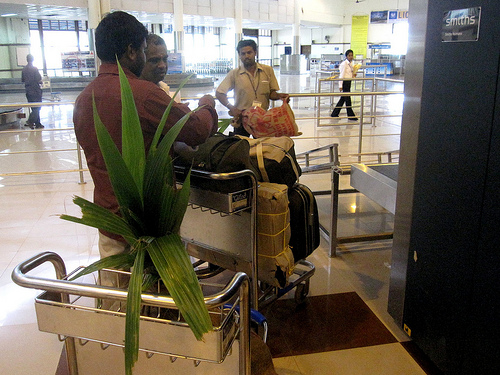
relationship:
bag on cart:
[193, 134, 262, 182] [171, 164, 317, 340]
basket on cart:
[94, 253, 171, 290] [6, 228, 260, 373]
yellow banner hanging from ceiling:
[350, 16, 370, 58] [116, 1, 407, 20]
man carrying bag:
[210, 33, 298, 137] [193, 134, 262, 182]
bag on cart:
[193, 130, 252, 186] [13, 161, 316, 373]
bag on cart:
[245, 131, 305, 188] [13, 161, 316, 373]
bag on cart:
[251, 180, 298, 284] [13, 161, 316, 373]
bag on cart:
[288, 182, 321, 260] [13, 161, 316, 373]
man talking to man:
[71, 11, 221, 310] [139, 28, 174, 98]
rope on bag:
[255, 211, 292, 220] [256, 182, 295, 289]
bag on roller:
[193, 134, 262, 182] [150, 147, 335, 323]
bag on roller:
[233, 134, 303, 188] [150, 147, 335, 323]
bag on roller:
[256, 182, 295, 289] [150, 147, 335, 323]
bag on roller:
[285, 182, 321, 264] [150, 147, 335, 323]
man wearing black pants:
[329, 49, 361, 121] [325, 82, 363, 115]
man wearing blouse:
[329, 49, 361, 121] [331, 61, 356, 84]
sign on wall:
[439, 8, 480, 43] [386, 0, 498, 373]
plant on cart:
[50, 53, 218, 374] [11, 248, 252, 373]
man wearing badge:
[215, 40, 290, 138] [246, 94, 266, 116]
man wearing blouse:
[329, 49, 361, 121] [338, 59, 354, 88]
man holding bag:
[215, 40, 290, 138] [244, 99, 293, 142]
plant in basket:
[50, 72, 218, 373] [9, 235, 264, 373]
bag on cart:
[256, 182, 295, 289] [13, 161, 316, 373]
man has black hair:
[215, 40, 290, 138] [237, 35, 258, 55]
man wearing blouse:
[330, 48, 370, 122] [338, 59, 354, 88]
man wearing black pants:
[329, 49, 361, 121] [331, 80, 356, 116]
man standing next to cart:
[71, 11, 221, 310] [13, 161, 316, 373]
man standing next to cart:
[136, 29, 183, 108] [13, 161, 316, 373]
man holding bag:
[215, 40, 290, 138] [241, 97, 298, 134]